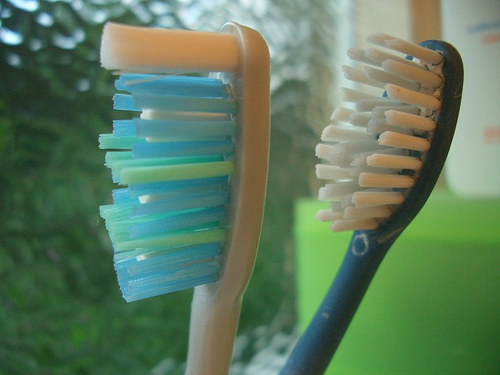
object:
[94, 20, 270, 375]
toothbrush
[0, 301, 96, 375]
grass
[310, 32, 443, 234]
bristle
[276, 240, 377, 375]
handle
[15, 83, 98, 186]
bush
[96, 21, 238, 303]
bristle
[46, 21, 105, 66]
leave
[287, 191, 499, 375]
plastic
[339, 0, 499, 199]
wall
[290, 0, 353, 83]
window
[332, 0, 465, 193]
board